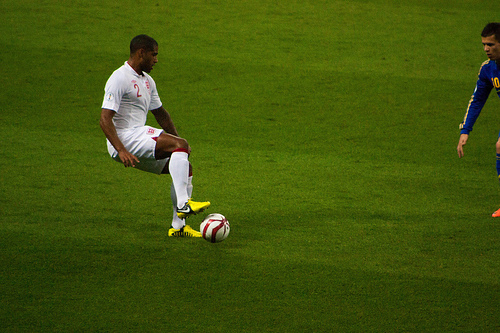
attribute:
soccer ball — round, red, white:
[199, 210, 231, 244]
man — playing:
[95, 32, 214, 241]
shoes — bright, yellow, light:
[169, 197, 211, 237]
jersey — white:
[101, 60, 162, 131]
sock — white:
[169, 148, 192, 209]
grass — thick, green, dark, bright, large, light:
[2, 0, 499, 332]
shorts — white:
[122, 124, 172, 175]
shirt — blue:
[454, 55, 499, 136]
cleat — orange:
[488, 205, 499, 221]